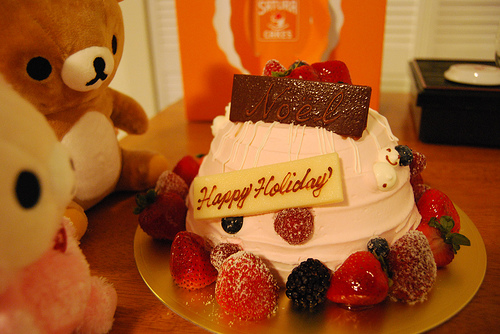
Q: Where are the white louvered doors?
A: Behind the table.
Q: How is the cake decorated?
A: For Christmas holiday.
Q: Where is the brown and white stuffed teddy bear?
A: Beside the cake.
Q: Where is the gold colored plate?
A: Under the cake.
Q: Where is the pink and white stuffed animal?
A: To the left of the cake.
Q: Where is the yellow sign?
A: On the cake.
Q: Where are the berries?
A: Around the cake.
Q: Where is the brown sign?
A: On top of the cake.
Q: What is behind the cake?
A: Orange sign.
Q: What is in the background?
A: Brown table.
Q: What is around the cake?
A: Teddy bears.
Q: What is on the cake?
A: White icing.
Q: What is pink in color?
A: The teddy bear.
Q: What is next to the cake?
A: Berries.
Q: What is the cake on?
A: Platter.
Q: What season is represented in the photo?
A: Christmas.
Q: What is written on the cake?
A: Happy Holidays.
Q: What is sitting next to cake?
A: Teddy bears.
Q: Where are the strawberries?
A: On platter.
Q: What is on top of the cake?
A: Chocolate.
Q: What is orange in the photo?
A: Box.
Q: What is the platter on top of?
A: Table.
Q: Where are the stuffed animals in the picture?
A: Left side.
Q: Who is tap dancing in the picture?
A: No one.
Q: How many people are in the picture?
A: None.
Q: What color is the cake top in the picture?
A: White.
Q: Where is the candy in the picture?
A: Top of the cake.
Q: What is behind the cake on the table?
A: A gift bag.